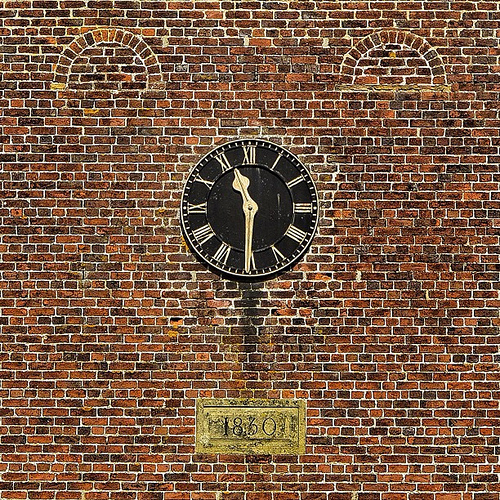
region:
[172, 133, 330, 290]
this is a clock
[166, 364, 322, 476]
this is an inscription on a wall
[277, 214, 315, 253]
a number on a wall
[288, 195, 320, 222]
a number on a wall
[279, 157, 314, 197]
a number on a wall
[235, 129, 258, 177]
a number on a wall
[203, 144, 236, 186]
a number on a wall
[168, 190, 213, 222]
a number on a wall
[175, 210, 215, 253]
a number on a wall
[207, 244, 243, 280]
a number on a wall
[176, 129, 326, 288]
the clock reads 11:30 and 30 seconds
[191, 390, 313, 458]
this wall/clock was constructed in 1830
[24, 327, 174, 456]
bricks were made by hand back then, so each brick is unique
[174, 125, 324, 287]
this clock uses Roman numerals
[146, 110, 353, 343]
the color change may indicate that some bricks have been replaced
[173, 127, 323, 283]
the face of the clock is black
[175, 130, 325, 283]
the clock has 60 hash marks, one for each minute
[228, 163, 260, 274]
the clock hands are brass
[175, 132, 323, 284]
the clock's numbers are white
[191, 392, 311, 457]
the year plate looks like brass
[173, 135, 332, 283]
clock on the building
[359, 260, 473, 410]
the building is made of bricks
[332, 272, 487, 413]
the bricks are brown and black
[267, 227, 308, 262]
roman numerials on the clock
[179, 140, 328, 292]
the clock is black and gold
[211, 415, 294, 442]
numbers on the wall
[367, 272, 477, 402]
building is made of bricks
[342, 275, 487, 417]
bricks on the wall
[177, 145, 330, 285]
a circle clock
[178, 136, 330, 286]
the clock is a circle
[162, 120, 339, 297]
clock on the brick wall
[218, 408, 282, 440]
black numbers on a gold background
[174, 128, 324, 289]
black and gold clock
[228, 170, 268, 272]
two thick gold clock hands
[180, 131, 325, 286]
roman numerals around the circumference of the clock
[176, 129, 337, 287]
clock indicating it's 11:30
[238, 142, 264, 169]
roman numeral for the number 12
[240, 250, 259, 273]
clock hand covering part of the roman numeral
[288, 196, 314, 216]
sideways roman numeral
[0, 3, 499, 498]
building is made of brick